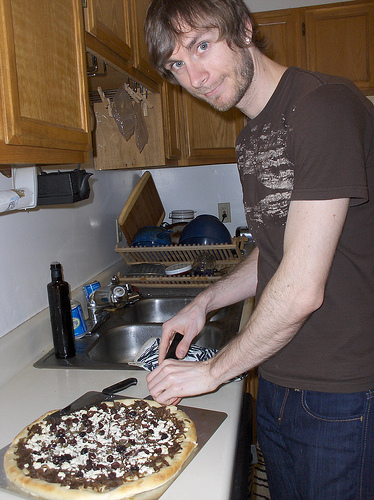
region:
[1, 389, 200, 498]
meat pizza on silver tray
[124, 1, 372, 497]
man cutting a pizza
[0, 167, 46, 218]
paper towel dispenser under cabinets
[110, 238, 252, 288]
dish strainer on counter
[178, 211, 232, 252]
blue bowl drying in dish strainer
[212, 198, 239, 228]
outlet cover on the wall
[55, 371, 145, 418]
knife with a black handle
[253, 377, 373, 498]
blue jeans of a man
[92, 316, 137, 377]
stainless steel sink in a kitchen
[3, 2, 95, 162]
oak cabinets in a kitchen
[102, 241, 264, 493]
Man about to slice a pizza.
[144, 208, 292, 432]
Man about to slice a pizza.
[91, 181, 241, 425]
Man about to slice a pizza.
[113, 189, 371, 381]
Man about to slice a pizza.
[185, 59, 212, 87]
Nose on a man who is touching a pizza.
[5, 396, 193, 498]
A whole pizza sitting on a counter.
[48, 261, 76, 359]
A tall black bottle sitting on the sink edge.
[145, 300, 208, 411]
Hands of a man wearing a brown shirt.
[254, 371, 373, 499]
Dark denim jeans on a man wearing a brown shirt.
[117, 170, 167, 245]
Brown cutting board.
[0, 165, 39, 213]
A white paper towel holder.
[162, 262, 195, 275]
A white lid in the dish drainer.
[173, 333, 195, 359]
Thumb on a man's right hand.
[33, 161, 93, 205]
A small black tea kettle hanging.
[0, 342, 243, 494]
A man cutting a pizza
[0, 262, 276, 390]
a man is standing next to a sink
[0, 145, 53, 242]
a paper towel holder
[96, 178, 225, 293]
Clean dishes in the dish strainer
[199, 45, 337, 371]
the man is wearing a brown shirt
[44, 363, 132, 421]
A serving knife next to the pizza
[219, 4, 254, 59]
The man has an earring in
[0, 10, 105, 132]
cabinets above the sink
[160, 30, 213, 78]
The man has blue eyes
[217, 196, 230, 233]
An outlet plug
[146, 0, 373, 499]
Man in the kitchen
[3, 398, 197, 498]
Pizza on a tray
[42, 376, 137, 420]
Knife on a tray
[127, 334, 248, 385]
Towel on the counter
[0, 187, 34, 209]
Paper towel on a roller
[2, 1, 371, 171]
Brown cabinets in the kitchen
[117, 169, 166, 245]
Cutting board on the dish holder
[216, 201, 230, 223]
Plug in on the wall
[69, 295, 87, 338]
Hand soap on the counter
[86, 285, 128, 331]
Faucet over the sink